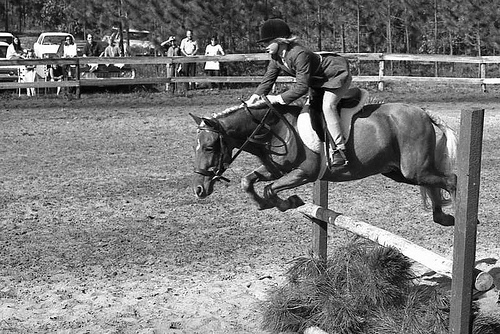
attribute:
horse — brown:
[191, 100, 461, 228]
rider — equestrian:
[249, 20, 353, 167]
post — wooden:
[449, 106, 488, 332]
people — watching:
[7, 29, 223, 74]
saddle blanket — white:
[298, 87, 370, 156]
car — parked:
[34, 29, 81, 69]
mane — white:
[207, 95, 267, 123]